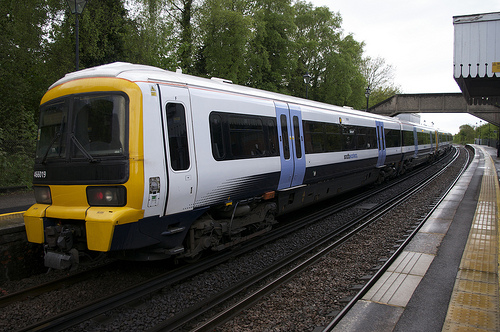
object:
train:
[22, 61, 453, 275]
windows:
[210, 111, 282, 161]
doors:
[272, 99, 294, 189]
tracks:
[0, 142, 470, 331]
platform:
[329, 142, 499, 331]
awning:
[450, 12, 499, 109]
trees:
[0, 0, 85, 183]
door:
[157, 84, 198, 216]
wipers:
[68, 114, 100, 163]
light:
[363, 85, 373, 97]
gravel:
[212, 158, 462, 331]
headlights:
[85, 186, 128, 207]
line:
[443, 141, 500, 330]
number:
[33, 170, 48, 179]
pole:
[365, 97, 370, 112]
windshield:
[34, 94, 125, 159]